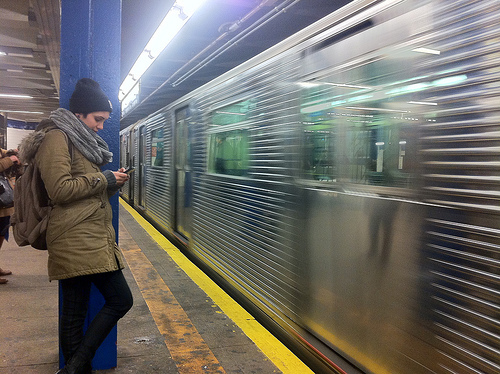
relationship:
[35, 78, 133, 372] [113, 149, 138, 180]
girl with phone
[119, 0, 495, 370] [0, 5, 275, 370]
train in platform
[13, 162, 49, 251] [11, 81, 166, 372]
backpack of person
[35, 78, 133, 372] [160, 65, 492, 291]
girl in train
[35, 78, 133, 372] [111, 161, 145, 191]
girl in phone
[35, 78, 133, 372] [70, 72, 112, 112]
girl in black hat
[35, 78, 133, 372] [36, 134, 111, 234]
girl in coat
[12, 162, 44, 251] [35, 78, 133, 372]
backpack of girl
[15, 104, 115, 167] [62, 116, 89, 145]
scarf around neck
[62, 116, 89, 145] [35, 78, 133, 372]
neck of girl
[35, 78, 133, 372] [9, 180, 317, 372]
girl on platform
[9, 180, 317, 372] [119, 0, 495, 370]
platform for train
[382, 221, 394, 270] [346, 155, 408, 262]
leg on passenger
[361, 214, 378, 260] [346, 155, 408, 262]
leg on passenger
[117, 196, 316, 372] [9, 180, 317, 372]
caution line painted on platform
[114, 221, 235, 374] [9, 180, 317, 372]
yellow line painted on platform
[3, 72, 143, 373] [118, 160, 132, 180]
girl using cell phone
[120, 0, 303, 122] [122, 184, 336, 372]
pipes over tracks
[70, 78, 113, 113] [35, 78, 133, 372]
black hat on girl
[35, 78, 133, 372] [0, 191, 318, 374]
girl standing on platform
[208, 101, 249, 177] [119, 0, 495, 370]
window on side of train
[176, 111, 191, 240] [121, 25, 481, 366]
door on side of train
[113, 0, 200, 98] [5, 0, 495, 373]
lights hanging in station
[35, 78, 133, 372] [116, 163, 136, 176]
girl looking at cell phone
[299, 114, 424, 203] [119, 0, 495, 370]
window on train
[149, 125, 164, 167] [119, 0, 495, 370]
window on train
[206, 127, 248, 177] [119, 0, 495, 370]
window on train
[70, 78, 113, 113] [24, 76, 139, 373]
black hat on person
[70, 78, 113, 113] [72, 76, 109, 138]
black hat on head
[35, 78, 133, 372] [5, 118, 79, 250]
girl carrying bag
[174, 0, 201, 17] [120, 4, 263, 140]
lights on ceiling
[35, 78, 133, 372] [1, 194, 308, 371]
girl standing on platform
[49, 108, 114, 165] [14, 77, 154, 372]
scarf around person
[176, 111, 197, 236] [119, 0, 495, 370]
door of train